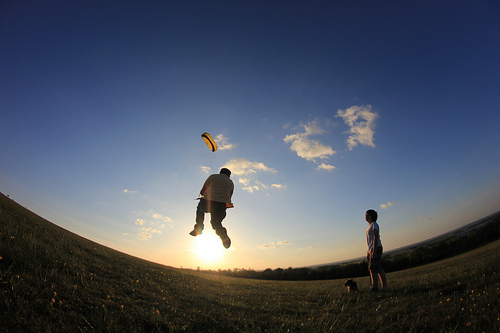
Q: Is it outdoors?
A: Yes, it is outdoors.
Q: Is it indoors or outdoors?
A: It is outdoors.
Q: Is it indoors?
A: No, it is outdoors.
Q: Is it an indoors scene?
A: No, it is outdoors.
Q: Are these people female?
A: No, they are both male and female.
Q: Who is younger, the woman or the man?
A: The woman is younger than the man.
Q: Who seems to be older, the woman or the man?
A: The man is older than the woman.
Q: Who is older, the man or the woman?
A: The man is older than the woman.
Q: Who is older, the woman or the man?
A: The man is older than the woman.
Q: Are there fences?
A: No, there are no fences.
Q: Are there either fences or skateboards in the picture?
A: No, there are no fences or skateboards.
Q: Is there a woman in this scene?
A: Yes, there is a woman.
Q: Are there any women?
A: Yes, there is a woman.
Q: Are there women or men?
A: Yes, there is a woman.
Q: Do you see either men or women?
A: Yes, there is a woman.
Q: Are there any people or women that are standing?
A: Yes, the woman is standing.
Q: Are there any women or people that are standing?
A: Yes, the woman is standing.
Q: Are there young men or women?
A: Yes, there is a young woman.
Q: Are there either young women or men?
A: Yes, there is a young woman.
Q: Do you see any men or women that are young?
A: Yes, the woman is young.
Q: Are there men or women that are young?
A: Yes, the woman is young.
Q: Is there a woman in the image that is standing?
A: Yes, there is a woman that is standing.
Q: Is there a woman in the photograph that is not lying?
A: Yes, there is a woman that is standing.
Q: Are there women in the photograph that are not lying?
A: Yes, there is a woman that is standing.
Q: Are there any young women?
A: Yes, there is a young woman.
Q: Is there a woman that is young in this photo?
A: Yes, there is a young woman.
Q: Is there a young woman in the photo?
A: Yes, there is a young woman.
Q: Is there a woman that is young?
A: Yes, there is a woman that is young.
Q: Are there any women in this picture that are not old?
A: Yes, there is an young woman.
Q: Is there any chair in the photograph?
A: No, there are no chairs.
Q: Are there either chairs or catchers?
A: No, there are no chairs or catchers.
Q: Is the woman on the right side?
A: Yes, the woman is on the right of the image.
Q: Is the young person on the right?
A: Yes, the woman is on the right of the image.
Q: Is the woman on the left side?
A: No, the woman is on the right of the image.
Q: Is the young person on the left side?
A: No, the woman is on the right of the image.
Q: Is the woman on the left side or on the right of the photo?
A: The woman is on the right of the image.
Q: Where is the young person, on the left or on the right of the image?
A: The woman is on the right of the image.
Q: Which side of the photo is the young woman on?
A: The woman is on the right of the image.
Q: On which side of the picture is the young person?
A: The woman is on the right of the image.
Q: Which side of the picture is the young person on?
A: The woman is on the right of the image.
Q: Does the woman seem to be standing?
A: Yes, the woman is standing.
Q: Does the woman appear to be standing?
A: Yes, the woman is standing.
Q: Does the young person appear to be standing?
A: Yes, the woman is standing.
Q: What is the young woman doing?
A: The woman is standing.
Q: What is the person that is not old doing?
A: The woman is standing.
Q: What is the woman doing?
A: The woman is standing.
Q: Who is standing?
A: The woman is standing.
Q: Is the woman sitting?
A: No, the woman is standing.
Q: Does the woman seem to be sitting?
A: No, the woman is standing.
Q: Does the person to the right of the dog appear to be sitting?
A: No, the woman is standing.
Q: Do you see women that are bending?
A: No, there is a woman but she is standing.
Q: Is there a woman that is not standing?
A: No, there is a woman but she is standing.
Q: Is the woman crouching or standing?
A: The woman is standing.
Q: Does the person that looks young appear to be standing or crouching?
A: The woman is standing.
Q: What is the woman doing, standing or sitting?
A: The woman is standing.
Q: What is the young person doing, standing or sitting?
A: The woman is standing.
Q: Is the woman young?
A: Yes, the woman is young.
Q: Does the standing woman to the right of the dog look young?
A: Yes, the woman is young.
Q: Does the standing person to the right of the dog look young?
A: Yes, the woman is young.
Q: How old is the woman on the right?
A: The woman is young.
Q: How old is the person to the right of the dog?
A: The woman is young.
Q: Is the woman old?
A: No, the woman is young.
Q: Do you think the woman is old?
A: No, the woman is young.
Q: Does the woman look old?
A: No, the woman is young.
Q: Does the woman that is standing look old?
A: No, the woman is young.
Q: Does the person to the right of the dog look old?
A: No, the woman is young.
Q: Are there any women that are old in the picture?
A: No, there is a woman but she is young.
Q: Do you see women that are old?
A: No, there is a woman but she is young.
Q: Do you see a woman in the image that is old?
A: No, there is a woman but she is young.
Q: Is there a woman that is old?
A: No, there is a woman but she is young.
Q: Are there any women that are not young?
A: No, there is a woman but she is young.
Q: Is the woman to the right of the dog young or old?
A: The woman is young.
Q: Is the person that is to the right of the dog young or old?
A: The woman is young.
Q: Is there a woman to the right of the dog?
A: Yes, there is a woman to the right of the dog.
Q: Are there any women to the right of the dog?
A: Yes, there is a woman to the right of the dog.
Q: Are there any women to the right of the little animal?
A: Yes, there is a woman to the right of the dog.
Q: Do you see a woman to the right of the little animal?
A: Yes, there is a woman to the right of the dog.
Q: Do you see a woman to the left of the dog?
A: No, the woman is to the right of the dog.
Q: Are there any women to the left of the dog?
A: No, the woman is to the right of the dog.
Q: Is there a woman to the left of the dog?
A: No, the woman is to the right of the dog.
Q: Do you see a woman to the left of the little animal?
A: No, the woman is to the right of the dog.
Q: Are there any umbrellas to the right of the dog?
A: No, there is a woman to the right of the dog.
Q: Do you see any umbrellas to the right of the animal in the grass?
A: No, there is a woman to the right of the dog.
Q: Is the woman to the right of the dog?
A: Yes, the woman is to the right of the dog.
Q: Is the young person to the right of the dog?
A: Yes, the woman is to the right of the dog.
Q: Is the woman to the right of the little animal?
A: Yes, the woman is to the right of the dog.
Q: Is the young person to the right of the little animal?
A: Yes, the woman is to the right of the dog.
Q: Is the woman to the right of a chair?
A: No, the woman is to the right of the dog.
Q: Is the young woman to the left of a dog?
A: No, the woman is to the right of a dog.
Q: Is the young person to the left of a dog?
A: No, the woman is to the right of a dog.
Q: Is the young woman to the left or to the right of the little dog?
A: The woman is to the right of the dog.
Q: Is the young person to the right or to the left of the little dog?
A: The woman is to the right of the dog.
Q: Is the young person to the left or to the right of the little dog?
A: The woman is to the right of the dog.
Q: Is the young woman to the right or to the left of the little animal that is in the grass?
A: The woman is to the right of the dog.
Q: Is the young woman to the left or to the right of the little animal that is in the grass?
A: The woman is to the right of the dog.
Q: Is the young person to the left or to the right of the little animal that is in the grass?
A: The woman is to the right of the dog.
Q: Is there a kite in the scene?
A: Yes, there is a kite.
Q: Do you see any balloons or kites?
A: Yes, there is a kite.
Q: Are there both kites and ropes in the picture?
A: No, there is a kite but no ropes.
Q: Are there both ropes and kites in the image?
A: No, there is a kite but no ropes.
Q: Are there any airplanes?
A: No, there are no airplanes.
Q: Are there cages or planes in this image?
A: No, there are no planes or cages.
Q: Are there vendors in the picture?
A: No, there are no vendors.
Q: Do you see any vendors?
A: No, there are no vendors.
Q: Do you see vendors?
A: No, there are no vendors.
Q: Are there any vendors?
A: No, there are no vendors.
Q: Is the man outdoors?
A: Yes, the man is outdoors.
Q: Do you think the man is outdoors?
A: Yes, the man is outdoors.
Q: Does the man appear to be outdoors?
A: Yes, the man is outdoors.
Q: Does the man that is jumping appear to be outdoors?
A: Yes, the man is outdoors.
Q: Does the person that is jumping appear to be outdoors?
A: Yes, the man is outdoors.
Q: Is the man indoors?
A: No, the man is outdoors.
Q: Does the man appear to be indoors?
A: No, the man is outdoors.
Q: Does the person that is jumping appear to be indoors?
A: No, the man is outdoors.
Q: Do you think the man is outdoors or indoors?
A: The man is outdoors.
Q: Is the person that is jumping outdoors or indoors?
A: The man is outdoors.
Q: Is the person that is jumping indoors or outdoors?
A: The man is outdoors.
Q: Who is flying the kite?
A: The man is flying the kite.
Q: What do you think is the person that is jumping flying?
A: The man is flying the kite.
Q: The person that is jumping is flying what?
A: The man is flying the kite.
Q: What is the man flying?
A: The man is flying the kite.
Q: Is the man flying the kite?
A: Yes, the man is flying the kite.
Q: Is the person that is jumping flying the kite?
A: Yes, the man is flying the kite.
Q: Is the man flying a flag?
A: No, the man is flying the kite.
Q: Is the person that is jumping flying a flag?
A: No, the man is flying the kite.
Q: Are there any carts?
A: No, there are no carts.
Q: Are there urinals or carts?
A: No, there are no carts or urinals.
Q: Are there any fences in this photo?
A: No, there are no fences.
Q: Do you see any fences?
A: No, there are no fences.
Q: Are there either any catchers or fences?
A: No, there are no fences or catchers.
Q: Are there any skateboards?
A: No, there are no skateboards.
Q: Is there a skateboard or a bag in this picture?
A: No, there are no skateboards or bags.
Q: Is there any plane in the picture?
A: No, there are no airplanes.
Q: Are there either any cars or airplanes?
A: No, there are no airplanes or cars.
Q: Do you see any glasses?
A: No, there are no glasses.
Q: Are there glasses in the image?
A: No, there are no glasses.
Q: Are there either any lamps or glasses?
A: No, there are no glasses or lamps.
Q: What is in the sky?
A: The clouds are in the sky.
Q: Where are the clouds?
A: The clouds are in the sky.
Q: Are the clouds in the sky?
A: Yes, the clouds are in the sky.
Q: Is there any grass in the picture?
A: Yes, there is grass.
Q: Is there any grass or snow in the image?
A: Yes, there is grass.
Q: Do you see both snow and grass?
A: No, there is grass but no snow.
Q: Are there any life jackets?
A: No, there are no life jackets.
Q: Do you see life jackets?
A: No, there are no life jackets.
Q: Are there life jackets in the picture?
A: No, there are no life jackets.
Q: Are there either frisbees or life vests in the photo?
A: No, there are no life vests or frisbees.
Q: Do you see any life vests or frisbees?
A: No, there are no life vests or frisbees.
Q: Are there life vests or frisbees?
A: No, there are no life vests or frisbees.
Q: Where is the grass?
A: The grass is in the field.